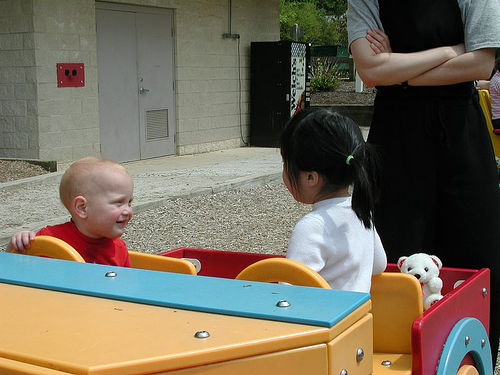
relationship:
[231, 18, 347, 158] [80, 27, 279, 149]
machine beside building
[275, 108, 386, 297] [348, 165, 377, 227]
children has a rubber band around hair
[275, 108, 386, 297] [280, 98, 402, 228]
children with hair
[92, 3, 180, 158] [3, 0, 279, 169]
doors to building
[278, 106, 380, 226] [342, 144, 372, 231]
hair in ponytail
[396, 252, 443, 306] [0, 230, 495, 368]
stuffed animal in train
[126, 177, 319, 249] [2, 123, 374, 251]
gravel on ground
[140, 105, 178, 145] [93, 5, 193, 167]
vent in door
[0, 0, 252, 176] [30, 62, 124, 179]
building made of cement blocks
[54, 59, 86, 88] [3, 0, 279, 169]
plate on building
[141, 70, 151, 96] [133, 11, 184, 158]
handle on door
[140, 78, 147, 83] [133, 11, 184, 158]
lock on door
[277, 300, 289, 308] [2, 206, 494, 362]
bolt on car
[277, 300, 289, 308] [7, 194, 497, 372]
bolt on train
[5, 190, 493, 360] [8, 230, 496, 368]
silver button on train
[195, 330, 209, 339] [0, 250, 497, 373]
bolt on train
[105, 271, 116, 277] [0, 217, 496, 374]
bolt on train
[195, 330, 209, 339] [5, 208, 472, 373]
bolt on train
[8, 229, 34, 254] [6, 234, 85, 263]
hands on seat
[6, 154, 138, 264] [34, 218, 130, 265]
boy wearing red shirt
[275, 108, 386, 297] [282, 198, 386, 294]
children has on shirt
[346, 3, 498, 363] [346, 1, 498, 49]
person wearing shirt